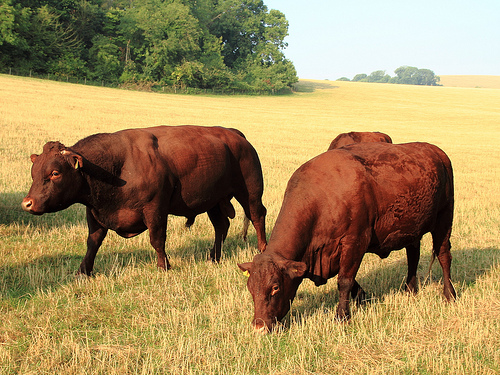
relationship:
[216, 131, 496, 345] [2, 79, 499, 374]
cow eating golden grass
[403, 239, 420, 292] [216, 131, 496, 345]
leg of cow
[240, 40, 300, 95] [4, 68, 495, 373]
tree on side of field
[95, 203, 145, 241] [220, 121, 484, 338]
brisket of cow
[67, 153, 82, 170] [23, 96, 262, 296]
cow ear of cow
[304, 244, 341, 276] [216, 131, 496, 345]
brisket of cow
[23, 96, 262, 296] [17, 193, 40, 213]
cow has nose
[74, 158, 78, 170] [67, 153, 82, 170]
tag on cow ear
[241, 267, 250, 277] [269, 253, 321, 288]
tag on ear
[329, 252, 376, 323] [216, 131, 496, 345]
front legs of cow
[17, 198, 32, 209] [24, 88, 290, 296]
nostrils of cow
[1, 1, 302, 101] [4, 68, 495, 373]
trees on side of field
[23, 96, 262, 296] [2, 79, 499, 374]
cow standing on golden grass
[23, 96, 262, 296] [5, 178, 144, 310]
cow facing left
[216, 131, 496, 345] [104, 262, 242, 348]
cow with its face in grass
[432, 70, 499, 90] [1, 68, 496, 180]
hill in background